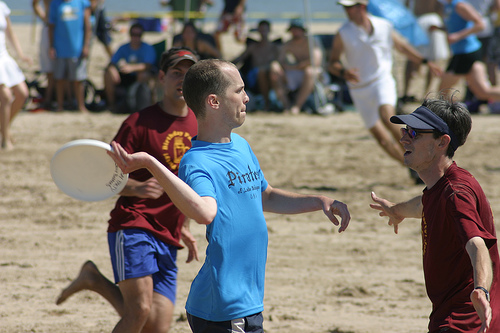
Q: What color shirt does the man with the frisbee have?
A: Blue.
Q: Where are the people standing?
A: On the sand.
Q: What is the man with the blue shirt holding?
A: Frisbee.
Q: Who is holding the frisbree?
A: The man in the blue shirt.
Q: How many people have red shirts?
A: 2.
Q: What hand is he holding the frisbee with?
A: Right.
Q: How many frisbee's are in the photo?
A: 1.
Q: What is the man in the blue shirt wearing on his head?
A: Nothing.